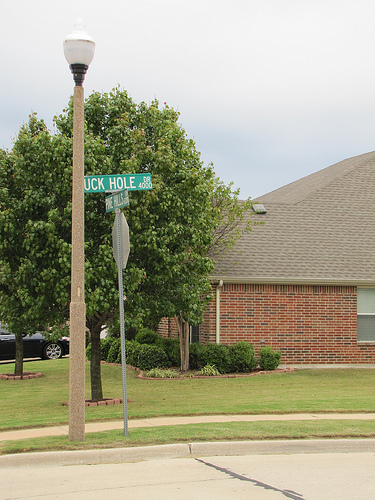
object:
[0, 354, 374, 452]
lawn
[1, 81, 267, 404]
tree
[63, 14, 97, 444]
lamp post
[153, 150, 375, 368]
house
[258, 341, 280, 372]
bushes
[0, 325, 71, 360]
car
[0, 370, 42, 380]
bricks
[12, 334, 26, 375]
bottom of tree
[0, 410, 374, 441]
sidewalk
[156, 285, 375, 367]
wall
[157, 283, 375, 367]
bricks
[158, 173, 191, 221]
leaves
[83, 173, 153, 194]
sign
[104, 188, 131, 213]
sign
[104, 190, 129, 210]
white writing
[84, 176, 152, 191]
white writing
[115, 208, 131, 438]
sign post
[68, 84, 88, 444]
post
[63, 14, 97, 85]
street light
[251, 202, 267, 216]
skylight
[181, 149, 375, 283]
roof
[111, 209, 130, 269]
stop sign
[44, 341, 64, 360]
car tire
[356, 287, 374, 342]
trim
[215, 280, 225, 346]
gutter downspout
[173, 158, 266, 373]
tree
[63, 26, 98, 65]
bulb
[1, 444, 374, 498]
road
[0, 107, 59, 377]
tree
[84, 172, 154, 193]
street names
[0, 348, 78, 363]
driveway